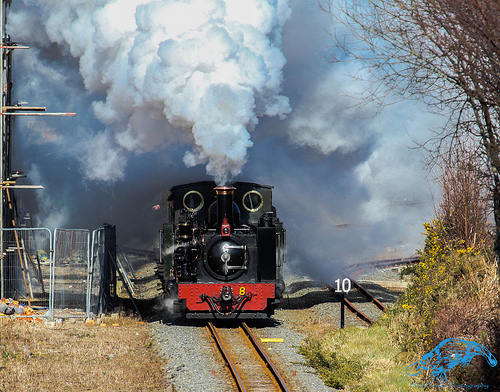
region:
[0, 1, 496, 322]
Steam train blowing steam.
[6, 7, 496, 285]
Billowing steam above the train.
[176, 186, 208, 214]
Round window on the front left side.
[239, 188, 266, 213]
A round window on the front right side.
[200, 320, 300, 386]
A steel train track.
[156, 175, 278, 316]
Train is black and red.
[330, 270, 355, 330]
A pole with a white number attached.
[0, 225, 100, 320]
A chain link fence.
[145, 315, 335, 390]
Rocks on both sides of the track.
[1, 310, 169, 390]
Dry grass next to the track.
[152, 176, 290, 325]
Train on the tracks.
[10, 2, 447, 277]
Smoke coming from the train.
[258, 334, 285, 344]
Yellow bar on the ground.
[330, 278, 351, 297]
White number on the track.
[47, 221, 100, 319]
Metal gate beside the train.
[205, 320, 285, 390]
Train tracks in front of the train.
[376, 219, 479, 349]
Yellow flowers on the bush.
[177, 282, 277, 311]
Red color on the front of the train.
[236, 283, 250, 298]
Yellow number on the train.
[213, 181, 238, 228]
Smoke stack on the train.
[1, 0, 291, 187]
white smoke billowing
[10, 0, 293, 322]
white smoke billowing from train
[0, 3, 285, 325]
white smoke billowing from black train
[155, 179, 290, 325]
train is black and red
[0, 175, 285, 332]
metal fence next to train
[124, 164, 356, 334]
The number 10 next to train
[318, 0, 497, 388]
bare tree, green bush and grass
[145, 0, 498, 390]
bare tree, green bush and grass next to train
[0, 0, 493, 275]
grey cloudy sky with billowing white smoke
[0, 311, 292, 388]
brown grass next to tracks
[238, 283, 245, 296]
a yellow number on a train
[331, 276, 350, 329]
the number 10 on a pole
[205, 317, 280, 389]
rusty yellow train tracks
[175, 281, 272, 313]
the red bumper to a train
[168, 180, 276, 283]
a black train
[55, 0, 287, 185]
smoke billowing out of a train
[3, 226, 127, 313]
a silver chain link fence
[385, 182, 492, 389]
green and orange foliage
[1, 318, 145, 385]
a patch of dying grass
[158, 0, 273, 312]
a train with smoke pouring out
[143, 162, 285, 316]
black train engine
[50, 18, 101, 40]
white clouds in blue sky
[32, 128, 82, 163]
white clouds in blue sky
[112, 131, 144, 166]
white clouds in blue sky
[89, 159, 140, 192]
white clouds in blue sky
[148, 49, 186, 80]
white clouds in blue sky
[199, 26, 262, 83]
white clouds in blue sky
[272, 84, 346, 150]
white clouds in blue sky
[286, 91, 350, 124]
white clouds in blue sky